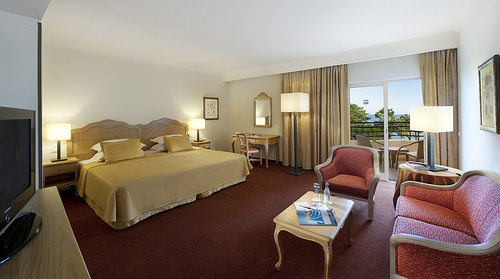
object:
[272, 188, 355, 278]
coffee table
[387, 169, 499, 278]
couch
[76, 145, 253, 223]
bed spread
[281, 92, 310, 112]
lamp shade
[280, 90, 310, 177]
floor lamp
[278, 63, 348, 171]
curtains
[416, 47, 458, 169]
curtains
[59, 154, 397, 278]
carpet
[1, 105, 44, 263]
television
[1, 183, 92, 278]
table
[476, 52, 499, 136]
art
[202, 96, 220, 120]
art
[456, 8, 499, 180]
wall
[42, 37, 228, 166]
wall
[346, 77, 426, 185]
french doors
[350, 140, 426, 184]
deck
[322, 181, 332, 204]
bottle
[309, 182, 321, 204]
glass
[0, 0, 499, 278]
bedroom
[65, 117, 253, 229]
bed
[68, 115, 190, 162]
headboard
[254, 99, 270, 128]
mirror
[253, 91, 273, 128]
frame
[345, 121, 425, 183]
balcony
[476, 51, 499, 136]
frame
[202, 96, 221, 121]
frame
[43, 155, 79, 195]
nightstand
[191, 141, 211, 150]
nightstand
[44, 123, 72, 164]
lamp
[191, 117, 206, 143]
lamp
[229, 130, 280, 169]
desk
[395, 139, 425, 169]
chair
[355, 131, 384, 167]
chair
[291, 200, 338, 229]
magazine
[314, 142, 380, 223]
armchair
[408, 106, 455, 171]
lamp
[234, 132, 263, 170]
desk chair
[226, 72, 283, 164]
wall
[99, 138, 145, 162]
pillows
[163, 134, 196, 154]
pillows